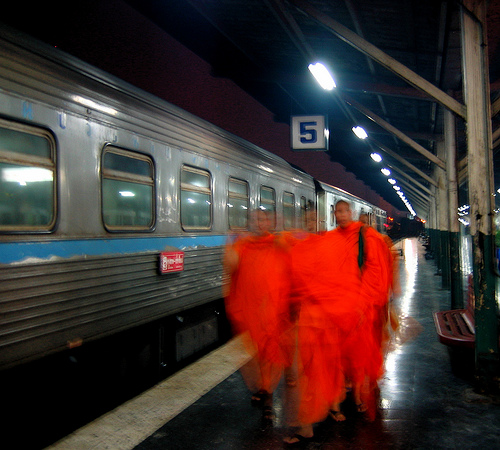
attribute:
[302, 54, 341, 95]
light — white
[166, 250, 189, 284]
sign — red, blue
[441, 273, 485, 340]
bench — brown, red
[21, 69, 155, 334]
train — gray, silver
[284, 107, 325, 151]
number — 5, blue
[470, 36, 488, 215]
pole — brown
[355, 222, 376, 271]
strap — black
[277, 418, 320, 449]
sandal — black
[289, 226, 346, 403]
gown — orange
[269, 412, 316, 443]
flip flop — black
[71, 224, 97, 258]
strip — blue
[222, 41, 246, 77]
sky — black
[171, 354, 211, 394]
line — white